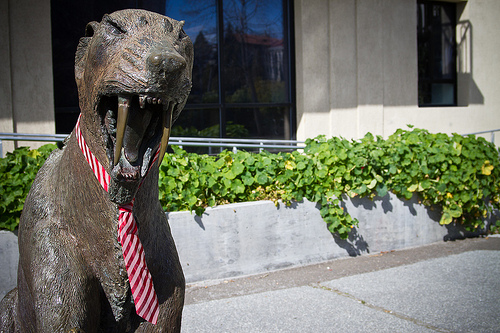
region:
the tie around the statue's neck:
[71, 111, 171, 321]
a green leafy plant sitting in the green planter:
[172, 128, 497, 230]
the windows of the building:
[58, 6, 301, 136]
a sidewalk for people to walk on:
[182, 233, 499, 330]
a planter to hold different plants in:
[160, 157, 441, 278]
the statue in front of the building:
[2, 9, 193, 331]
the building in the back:
[2, 1, 499, 146]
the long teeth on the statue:
[112, 98, 174, 173]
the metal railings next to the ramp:
[1, 130, 310, 157]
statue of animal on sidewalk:
[3, 14, 205, 331]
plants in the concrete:
[6, 125, 488, 210]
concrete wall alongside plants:
[175, 198, 464, 263]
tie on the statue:
[71, 135, 178, 325]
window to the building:
[414, 18, 456, 101]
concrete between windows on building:
[303, 18, 404, 130]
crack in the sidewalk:
[305, 278, 389, 303]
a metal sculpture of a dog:
[8, 7, 190, 332]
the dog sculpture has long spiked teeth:
[82, 77, 179, 200]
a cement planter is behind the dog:
[1, 142, 493, 279]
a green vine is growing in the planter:
[5, 128, 499, 237]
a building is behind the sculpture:
[1, 6, 498, 256]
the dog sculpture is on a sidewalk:
[6, 99, 498, 324]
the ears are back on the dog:
[69, 14, 201, 108]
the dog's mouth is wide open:
[90, 76, 189, 200]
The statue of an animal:
[11, 9, 231, 331]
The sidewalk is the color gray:
[278, 262, 488, 330]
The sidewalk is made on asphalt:
[282, 259, 472, 330]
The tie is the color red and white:
[70, 99, 162, 329]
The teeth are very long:
[106, 94, 176, 173]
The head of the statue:
[61, 4, 205, 208]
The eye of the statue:
[98, 12, 133, 40]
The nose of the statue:
[143, 45, 188, 92]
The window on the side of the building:
[192, 10, 312, 152]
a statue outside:
[29, 22, 313, 326]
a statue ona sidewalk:
[54, 30, 311, 298]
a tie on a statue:
[33, 43, 236, 314]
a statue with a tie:
[41, 31, 176, 325]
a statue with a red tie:
[54, 54, 317, 331]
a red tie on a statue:
[49, 36, 268, 327]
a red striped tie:
[61, 118, 203, 303]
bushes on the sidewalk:
[207, 137, 397, 224]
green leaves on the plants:
[472, 172, 486, 208]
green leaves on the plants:
[354, 134, 386, 165]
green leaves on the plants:
[311, 174, 358, 207]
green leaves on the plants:
[256, 158, 296, 195]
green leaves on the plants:
[229, 156, 268, 193]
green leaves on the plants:
[183, 153, 221, 205]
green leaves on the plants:
[190, 165, 216, 192]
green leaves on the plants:
[1, 144, 34, 176]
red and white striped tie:
[58, 100, 189, 328]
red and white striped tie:
[71, 114, 174, 322]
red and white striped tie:
[54, 108, 191, 325]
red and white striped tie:
[57, 105, 195, 325]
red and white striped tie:
[64, 106, 190, 321]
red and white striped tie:
[53, 114, 186, 320]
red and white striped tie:
[51, 112, 192, 328]